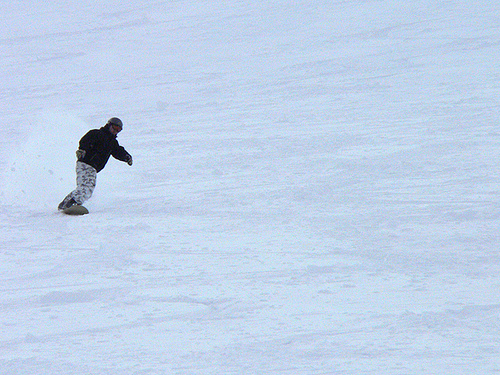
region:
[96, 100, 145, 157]
face of the man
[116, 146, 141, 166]
hand of the man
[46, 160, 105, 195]
legs of the man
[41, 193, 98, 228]
shoe of the man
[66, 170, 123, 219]
a man waring pant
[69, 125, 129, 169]
a man wearing shirt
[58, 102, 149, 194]
a man wearing jacket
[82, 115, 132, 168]
a man wearing black jacket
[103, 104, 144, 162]
a man wearing hat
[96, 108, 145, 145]
a man wearing mask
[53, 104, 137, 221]
snowboarder coming down the mountain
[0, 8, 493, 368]
snow covered mountainside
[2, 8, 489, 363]
snow the snowboarder is boarding on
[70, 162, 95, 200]
white pants with print snowboarder is wearing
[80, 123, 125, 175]
black coat the snowboarder is wearing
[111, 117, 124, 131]
knit cap the snowboarder is wearing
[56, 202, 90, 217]
snowboard in the snow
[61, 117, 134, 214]
man riding a snowboard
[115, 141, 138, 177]
extended arm of the snowboarder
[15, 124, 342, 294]
tracks in the snowfall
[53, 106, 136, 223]
the man is snowboarding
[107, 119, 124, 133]
man is wearing goggles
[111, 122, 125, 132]
the goggles are orange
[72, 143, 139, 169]
person is wearing gloves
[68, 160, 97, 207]
person's pants are white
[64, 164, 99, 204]
black design on pants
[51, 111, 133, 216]
person snowboarding down hill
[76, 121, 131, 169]
person's jacket is black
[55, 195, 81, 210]
person's shoes are black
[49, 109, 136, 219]
person is snowboarding alone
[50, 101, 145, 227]
Young man snowboarding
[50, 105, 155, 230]
Young man snowboarding on a cold day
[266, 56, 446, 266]
Side of a snowy mountain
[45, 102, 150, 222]
Man in snow gear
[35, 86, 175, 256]
Man snowboarding downhill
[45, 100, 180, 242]
Man keeping balance while snowboarding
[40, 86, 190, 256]
Downhill snowboard practice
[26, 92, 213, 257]
Young man in snow gear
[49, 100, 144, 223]
The man is snowboarding.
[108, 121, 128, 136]
The man is wearing googles.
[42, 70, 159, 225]
The man is the only person skiing.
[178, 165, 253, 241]
The snow is white.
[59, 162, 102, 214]
The man is wearing camauflage pants.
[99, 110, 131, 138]
The man is wearing a ski hat.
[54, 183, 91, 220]
Both legs are on the floor.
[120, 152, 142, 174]
The man is wearing gloves.